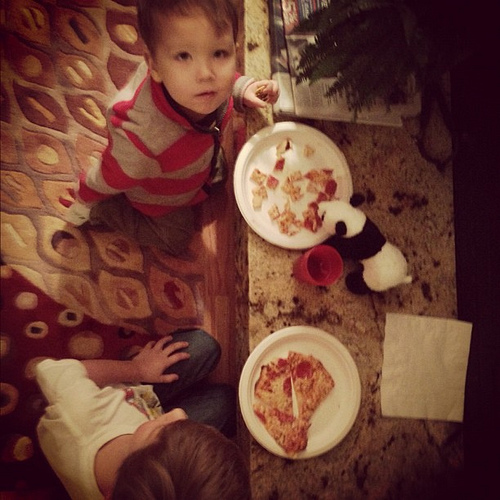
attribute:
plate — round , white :
[226, 131, 367, 245]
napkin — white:
[378, 313, 473, 421]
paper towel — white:
[383, 306, 478, 441]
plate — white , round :
[219, 317, 373, 458]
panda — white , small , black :
[303, 164, 458, 335]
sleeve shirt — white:
[12, 353, 158, 483]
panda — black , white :
[313, 192, 415, 298]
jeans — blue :
[152, 326, 237, 436]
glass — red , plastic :
[297, 244, 343, 288]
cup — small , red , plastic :
[299, 248, 349, 297]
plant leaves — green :
[282, 2, 477, 110]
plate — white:
[238, 324, 361, 458]